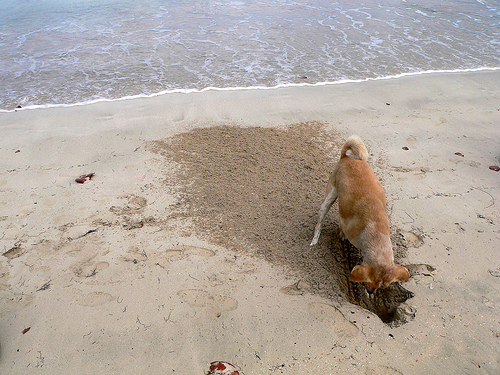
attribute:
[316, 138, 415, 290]
dog — digging, brown, white, small, orange, furry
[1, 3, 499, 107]
water — foamy, ocean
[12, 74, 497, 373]
sand — beach, white, smooth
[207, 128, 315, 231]
sand — loose, darker, stirred up, dug up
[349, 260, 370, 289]
ear — brown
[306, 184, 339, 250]
leg — white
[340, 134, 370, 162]
tail — tan